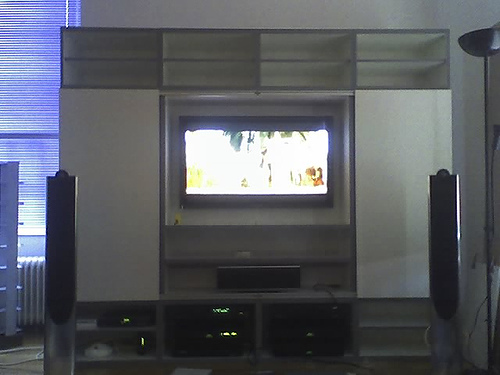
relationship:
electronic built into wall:
[180, 110, 335, 210] [142, 90, 467, 274]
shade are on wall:
[0, 0, 79, 238] [7, 6, 156, 371]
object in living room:
[1, 150, 30, 355] [1, 1, 499, 372]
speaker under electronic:
[211, 259, 311, 294] [180, 110, 335, 210]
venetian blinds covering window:
[5, 6, 61, 160] [4, 4, 76, 252]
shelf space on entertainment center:
[59, 27, 451, 90] [47, 24, 464, 374]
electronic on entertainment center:
[93, 303, 160, 328] [47, 24, 464, 374]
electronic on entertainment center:
[174, 300, 251, 359] [47, 24, 464, 374]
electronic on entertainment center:
[267, 299, 349, 359] [47, 24, 464, 374]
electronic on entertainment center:
[137, 329, 152, 358] [47, 24, 464, 374]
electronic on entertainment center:
[174, 110, 339, 212] [47, 24, 464, 374]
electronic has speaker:
[180, 110, 335, 210] [40, 165, 85, 373]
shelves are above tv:
[55, 19, 457, 95] [164, 97, 369, 242]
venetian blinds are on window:
[0, 0, 85, 237] [4, 4, 76, 252]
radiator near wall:
[15, 252, 48, 330] [2, 172, 158, 348]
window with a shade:
[1, 5, 86, 260] [4, 5, 56, 246]